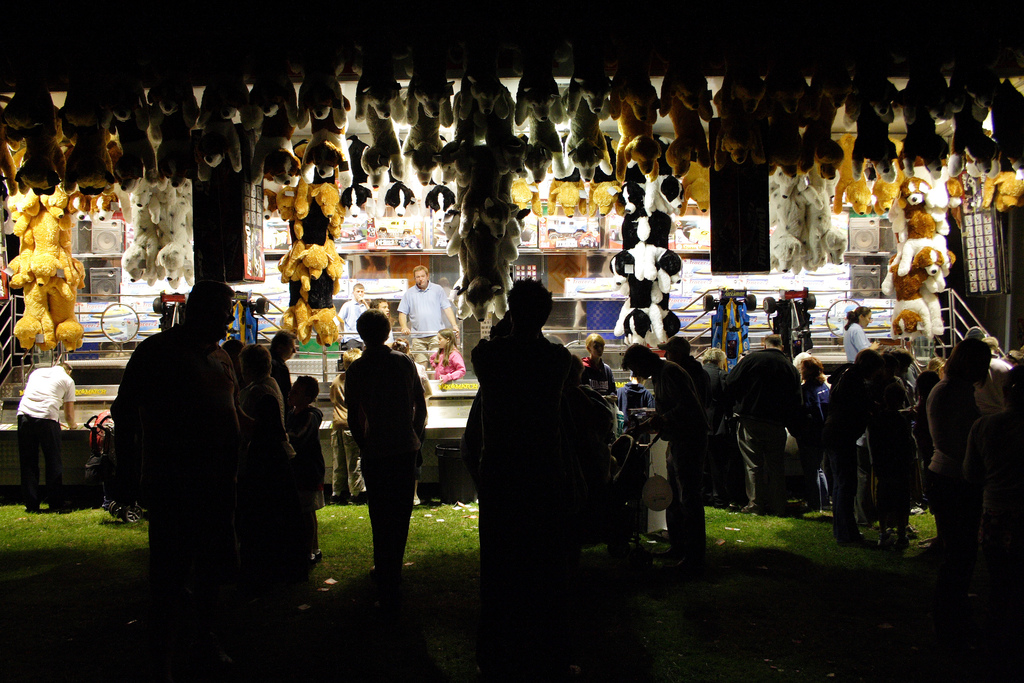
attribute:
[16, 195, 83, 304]
animal — stuffed, yellow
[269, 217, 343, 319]
animal — yellow, stuffed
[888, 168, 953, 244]
stuffed animal — brown, white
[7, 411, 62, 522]
pants — black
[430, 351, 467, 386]
sweatshirt — pink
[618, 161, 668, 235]
plush — black, white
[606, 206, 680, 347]
animal — STUFFED, WHITE, BLACK